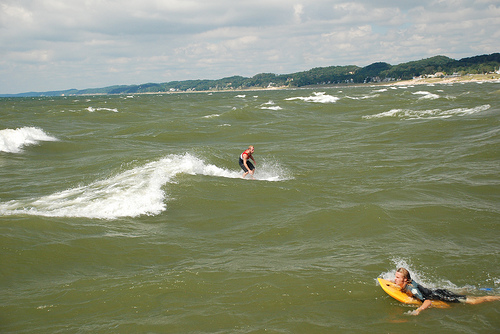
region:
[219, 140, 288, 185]
Man surfing on a wave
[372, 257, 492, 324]
Man floating on a surfboard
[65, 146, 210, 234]
Small white capped waves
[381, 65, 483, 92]
Beach along the shoreline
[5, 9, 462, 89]
Sky heavy with clouds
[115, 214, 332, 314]
Greenish brown water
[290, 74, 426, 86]
Structures along the shoreline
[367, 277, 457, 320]
Yellow surfboard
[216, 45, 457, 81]
Green hills above the water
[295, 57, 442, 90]
Shadow of clouds on the hillside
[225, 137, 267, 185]
man surfing in the ocean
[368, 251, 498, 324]
man riding a surfboard on his stomach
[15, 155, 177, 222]
white capped waves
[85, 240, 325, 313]
murky green water in the ocean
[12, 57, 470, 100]
hills behind the ocean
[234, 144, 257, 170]
red shirt on a surfer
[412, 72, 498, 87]
sand on the beach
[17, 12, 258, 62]
gray clouds in the sky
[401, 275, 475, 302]
a black wet suit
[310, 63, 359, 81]
tree covered hill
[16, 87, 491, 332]
the water is green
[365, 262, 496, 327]
a person on a surfboard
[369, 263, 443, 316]
the surfboard is yellow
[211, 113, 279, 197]
a person surfing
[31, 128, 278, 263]
the wave is white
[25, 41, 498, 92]
mountains by the water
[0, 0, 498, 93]
the sky is cloudy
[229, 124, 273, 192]
the person is wearing red and black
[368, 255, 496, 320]
the person has blonde hair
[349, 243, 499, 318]
the person is laying on the surfboard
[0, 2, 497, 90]
a blue cloudy sky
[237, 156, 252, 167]
black shorts on a man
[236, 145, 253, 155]
an orange vest on a man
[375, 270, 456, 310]
a yellow board under a man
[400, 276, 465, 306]
a black and grey wetsuit on a man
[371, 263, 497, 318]
a man riding a board in the water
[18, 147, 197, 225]
a white topped wave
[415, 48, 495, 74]
a treed hillside behind the beach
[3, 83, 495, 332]
grey green water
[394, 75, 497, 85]
a strip of beach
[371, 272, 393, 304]
the board is yellow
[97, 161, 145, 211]
the water is white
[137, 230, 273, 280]
the water is green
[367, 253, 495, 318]
the man is bodyboarding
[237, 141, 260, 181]
the man is surfing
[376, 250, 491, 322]
the man is lying on board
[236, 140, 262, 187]
the man is standing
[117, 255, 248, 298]
the water is dark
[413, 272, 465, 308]
the bodysuit is black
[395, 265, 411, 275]
the hair is blonde